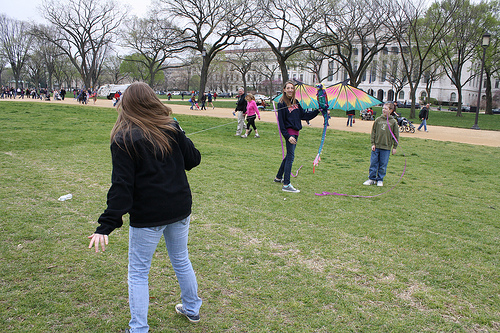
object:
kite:
[272, 78, 385, 174]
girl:
[83, 81, 203, 332]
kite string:
[183, 100, 315, 137]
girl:
[276, 81, 331, 195]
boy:
[362, 102, 399, 187]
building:
[310, 18, 497, 111]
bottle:
[57, 192, 73, 201]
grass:
[3, 99, 499, 331]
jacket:
[245, 100, 261, 118]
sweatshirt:
[371, 114, 402, 151]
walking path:
[0, 90, 499, 151]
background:
[0, 1, 497, 126]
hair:
[107, 81, 181, 159]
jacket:
[89, 123, 202, 236]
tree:
[155, 3, 257, 104]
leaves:
[146, 11, 158, 19]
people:
[243, 94, 264, 139]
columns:
[378, 45, 385, 83]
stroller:
[393, 115, 416, 133]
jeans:
[121, 217, 204, 331]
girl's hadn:
[317, 105, 330, 114]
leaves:
[437, 45, 445, 51]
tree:
[417, 1, 498, 114]